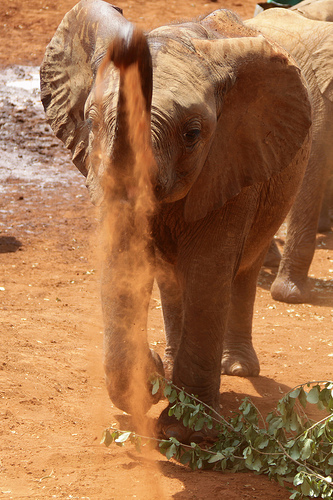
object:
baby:
[55, 2, 316, 442]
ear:
[38, 2, 109, 181]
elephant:
[41, 0, 313, 439]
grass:
[153, 375, 332, 489]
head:
[108, 39, 318, 164]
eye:
[176, 118, 205, 145]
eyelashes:
[78, 115, 92, 128]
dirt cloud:
[93, 66, 162, 479]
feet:
[156, 389, 215, 447]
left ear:
[185, 35, 310, 224]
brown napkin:
[30, 18, 310, 204]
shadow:
[1, 227, 27, 257]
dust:
[90, 24, 153, 459]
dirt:
[3, 86, 65, 206]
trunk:
[90, 19, 177, 207]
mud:
[0, 50, 87, 241]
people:
[33, 23, 311, 196]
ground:
[15, 127, 52, 206]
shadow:
[109, 368, 332, 498]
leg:
[221, 281, 263, 376]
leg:
[166, 252, 234, 445]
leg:
[91, 240, 157, 407]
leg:
[151, 273, 180, 392]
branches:
[102, 368, 331, 498]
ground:
[1, 0, 330, 497]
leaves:
[110, 372, 331, 489]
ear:
[183, 33, 310, 225]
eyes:
[81, 108, 96, 140]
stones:
[260, 304, 317, 343]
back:
[147, 15, 265, 105]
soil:
[91, 115, 199, 442]